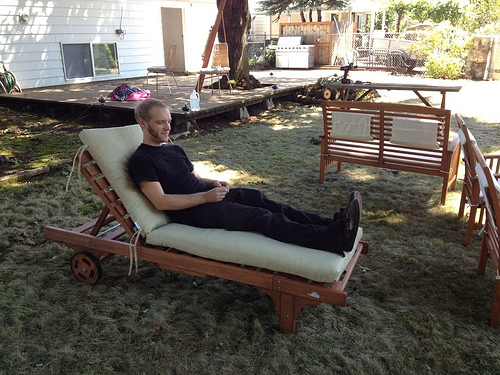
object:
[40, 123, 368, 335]
lounge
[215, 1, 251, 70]
tree trunk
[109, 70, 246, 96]
deck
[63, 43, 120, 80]
screen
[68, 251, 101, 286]
wheel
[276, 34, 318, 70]
grill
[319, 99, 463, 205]
bench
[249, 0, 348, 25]
tree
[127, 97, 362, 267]
man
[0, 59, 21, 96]
hose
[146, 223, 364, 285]
cushion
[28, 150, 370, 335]
chair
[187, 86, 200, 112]
bottle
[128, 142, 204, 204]
shirt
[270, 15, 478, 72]
fence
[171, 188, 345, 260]
pants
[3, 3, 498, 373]
not shown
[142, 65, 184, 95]
chair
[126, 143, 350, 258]
clothing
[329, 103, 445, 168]
cushions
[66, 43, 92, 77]
window